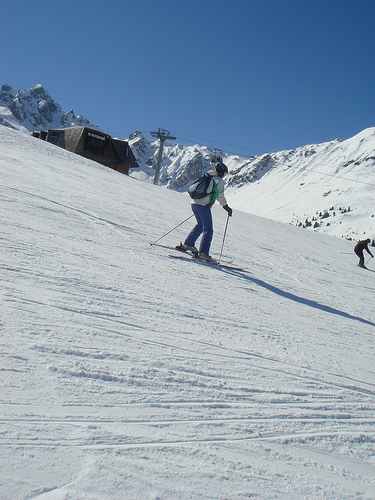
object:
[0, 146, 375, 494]
snow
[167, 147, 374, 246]
slopes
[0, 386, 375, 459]
tracks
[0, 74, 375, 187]
mountains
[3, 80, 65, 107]
snow caps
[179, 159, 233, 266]
skier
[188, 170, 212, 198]
backpack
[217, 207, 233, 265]
poles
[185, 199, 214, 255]
pants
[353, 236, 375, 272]
skier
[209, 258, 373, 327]
shadow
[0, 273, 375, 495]
ground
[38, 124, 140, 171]
building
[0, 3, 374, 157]
sky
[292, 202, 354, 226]
pines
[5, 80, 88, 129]
rocks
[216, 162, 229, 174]
cap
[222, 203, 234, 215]
gloves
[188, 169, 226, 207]
jacket